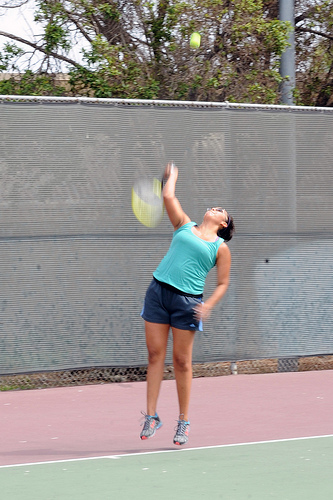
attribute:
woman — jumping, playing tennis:
[138, 161, 235, 446]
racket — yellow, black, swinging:
[128, 157, 173, 232]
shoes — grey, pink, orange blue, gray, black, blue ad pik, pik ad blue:
[137, 410, 191, 448]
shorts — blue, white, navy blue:
[140, 277, 205, 331]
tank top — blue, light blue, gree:
[150, 218, 224, 296]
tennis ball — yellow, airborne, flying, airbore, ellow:
[185, 29, 201, 52]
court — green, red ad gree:
[0, 368, 331, 499]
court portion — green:
[0, 432, 332, 499]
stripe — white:
[1, 432, 332, 468]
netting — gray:
[1, 105, 332, 375]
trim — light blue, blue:
[196, 296, 204, 334]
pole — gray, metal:
[274, 0, 300, 274]